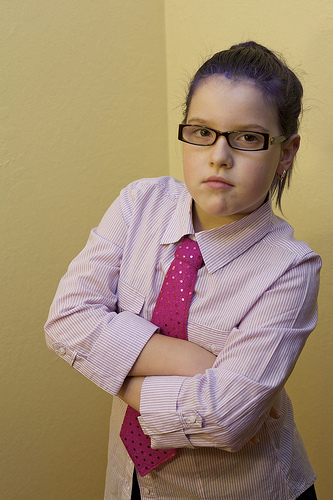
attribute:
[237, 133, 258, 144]
eye — brown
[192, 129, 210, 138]
eye — brown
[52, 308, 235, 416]
arms — crossed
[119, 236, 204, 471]
tie — pink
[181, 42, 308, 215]
hair — brown